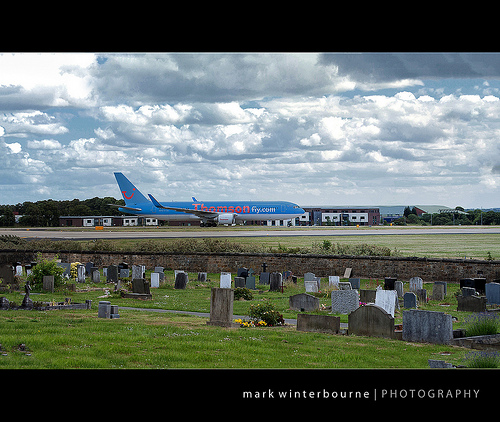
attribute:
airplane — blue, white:
[104, 169, 307, 231]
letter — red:
[190, 201, 201, 214]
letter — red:
[200, 201, 209, 216]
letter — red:
[208, 206, 217, 216]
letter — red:
[215, 204, 228, 214]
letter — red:
[235, 206, 244, 214]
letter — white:
[268, 206, 277, 214]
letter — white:
[264, 207, 270, 214]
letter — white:
[259, 206, 267, 215]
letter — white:
[253, 206, 262, 215]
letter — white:
[250, 204, 256, 216]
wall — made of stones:
[0, 248, 499, 289]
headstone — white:
[372, 287, 399, 320]